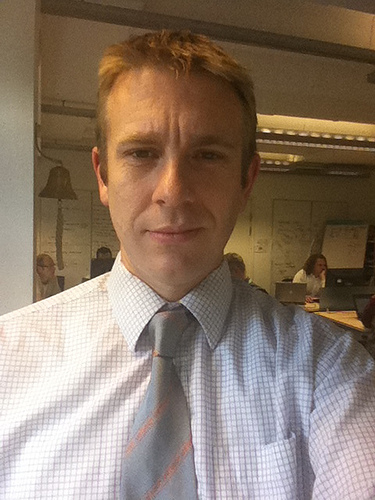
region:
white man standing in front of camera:
[3, 7, 363, 491]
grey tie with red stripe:
[111, 296, 194, 495]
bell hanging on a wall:
[30, 115, 71, 268]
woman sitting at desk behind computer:
[273, 245, 367, 302]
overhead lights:
[1, 116, 370, 180]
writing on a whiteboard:
[34, 185, 136, 298]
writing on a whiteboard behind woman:
[270, 190, 351, 299]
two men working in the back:
[31, 245, 116, 298]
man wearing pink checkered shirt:
[0, 263, 368, 495]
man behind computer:
[80, 240, 120, 283]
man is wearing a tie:
[113, 270, 225, 492]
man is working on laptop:
[287, 238, 341, 314]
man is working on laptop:
[265, 225, 358, 318]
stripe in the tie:
[127, 377, 184, 449]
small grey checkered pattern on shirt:
[208, 364, 280, 412]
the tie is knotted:
[142, 307, 196, 360]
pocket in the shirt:
[257, 427, 306, 498]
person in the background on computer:
[291, 249, 330, 304]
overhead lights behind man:
[259, 124, 372, 152]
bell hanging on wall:
[35, 123, 80, 206]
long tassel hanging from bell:
[54, 199, 70, 270]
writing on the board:
[75, 199, 110, 252]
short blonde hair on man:
[90, 25, 265, 194]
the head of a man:
[70, 32, 322, 329]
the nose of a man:
[137, 166, 205, 218]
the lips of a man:
[118, 202, 249, 265]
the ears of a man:
[60, 144, 126, 225]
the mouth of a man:
[129, 210, 234, 274]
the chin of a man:
[112, 242, 234, 312]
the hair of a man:
[47, 26, 307, 256]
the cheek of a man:
[100, 151, 177, 257]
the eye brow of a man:
[187, 126, 241, 154]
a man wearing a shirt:
[56, 161, 305, 381]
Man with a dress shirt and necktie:
[2, 34, 369, 499]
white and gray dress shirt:
[3, 251, 371, 498]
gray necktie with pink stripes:
[121, 310, 199, 498]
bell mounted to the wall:
[38, 141, 84, 272]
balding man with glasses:
[35, 255, 56, 296]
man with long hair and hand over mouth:
[291, 254, 326, 303]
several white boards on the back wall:
[43, 192, 358, 288]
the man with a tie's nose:
[154, 159, 193, 205]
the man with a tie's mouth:
[145, 225, 200, 240]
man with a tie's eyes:
[126, 147, 225, 164]